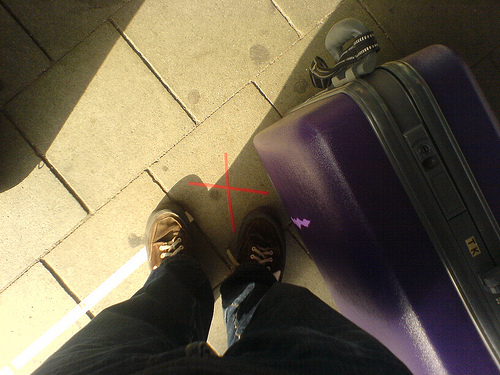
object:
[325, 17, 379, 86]
handle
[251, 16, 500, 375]
suitcase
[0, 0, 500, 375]
ground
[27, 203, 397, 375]
person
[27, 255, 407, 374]
pants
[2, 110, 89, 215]
grout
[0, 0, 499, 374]
tiles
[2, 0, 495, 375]
walkway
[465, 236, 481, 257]
sticker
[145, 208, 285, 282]
shoes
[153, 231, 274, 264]
laces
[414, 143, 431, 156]
lock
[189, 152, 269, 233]
x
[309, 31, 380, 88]
strap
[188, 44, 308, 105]
spots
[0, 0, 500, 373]
floor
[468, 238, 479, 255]
initials